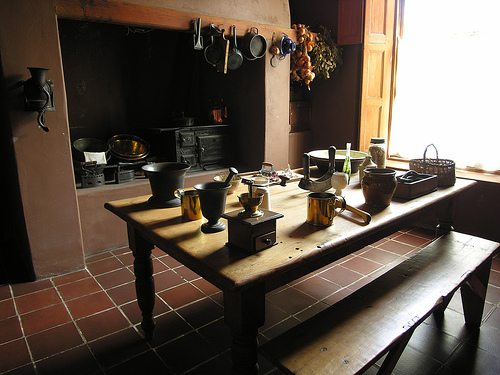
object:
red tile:
[18, 303, 74, 336]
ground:
[0, 225, 500, 374]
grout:
[71, 320, 88, 345]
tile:
[63, 288, 117, 321]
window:
[388, 0, 500, 175]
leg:
[223, 287, 269, 374]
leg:
[124, 218, 158, 340]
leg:
[436, 200, 458, 235]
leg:
[459, 260, 491, 326]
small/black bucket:
[138, 162, 192, 207]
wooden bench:
[258, 230, 500, 374]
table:
[104, 166, 479, 374]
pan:
[240, 27, 270, 62]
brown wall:
[0, 0, 289, 279]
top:
[236, 191, 269, 219]